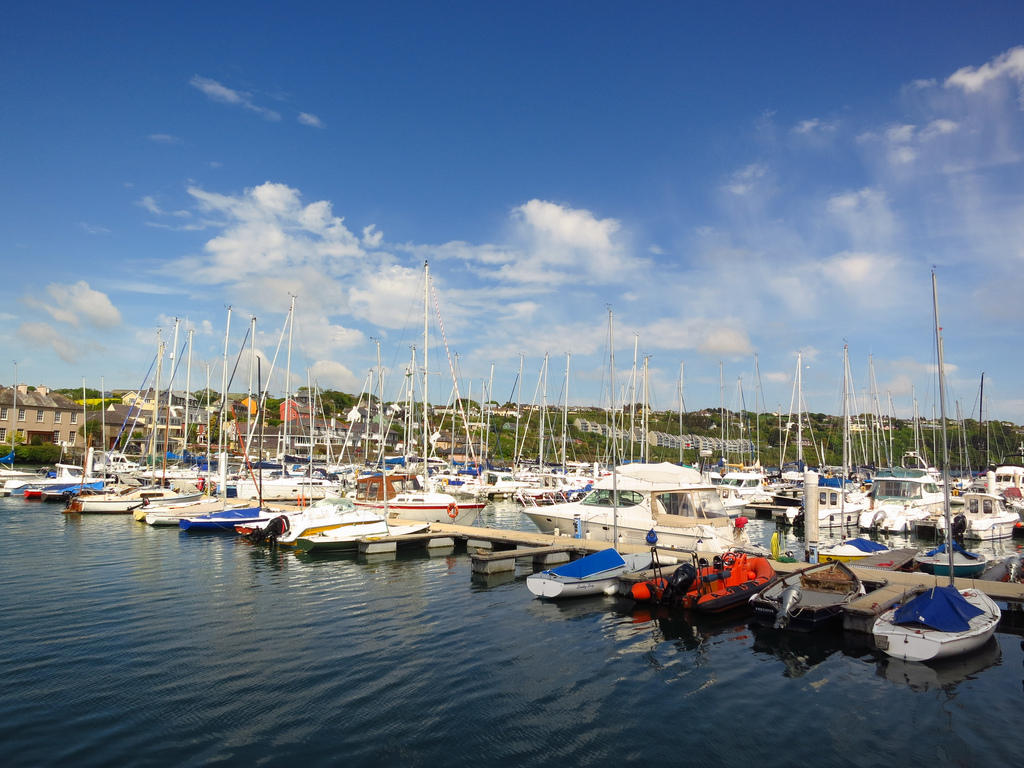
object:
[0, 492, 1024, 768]
water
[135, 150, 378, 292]
fluffy cloud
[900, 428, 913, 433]
leaves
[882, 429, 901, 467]
tree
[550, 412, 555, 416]
leaves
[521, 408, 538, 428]
tree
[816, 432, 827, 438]
leaves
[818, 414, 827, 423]
tree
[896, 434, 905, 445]
leaves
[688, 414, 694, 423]
leaves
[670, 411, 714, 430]
tree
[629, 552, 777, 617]
boat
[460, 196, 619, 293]
cloud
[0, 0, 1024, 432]
sky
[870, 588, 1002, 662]
boat